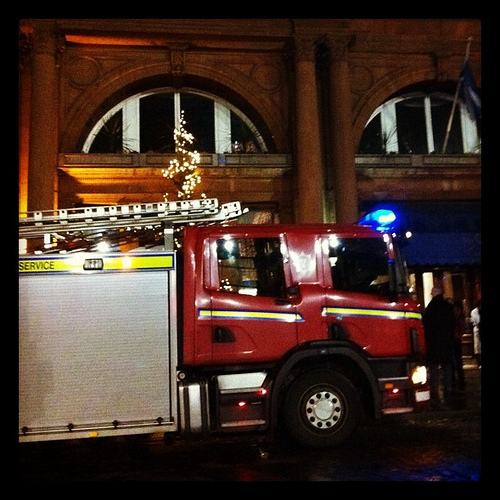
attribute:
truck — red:
[16, 200, 435, 447]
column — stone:
[287, 35, 328, 223]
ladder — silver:
[37, 200, 252, 252]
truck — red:
[184, 202, 438, 424]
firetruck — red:
[0, 193, 435, 458]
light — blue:
[346, 200, 409, 230]